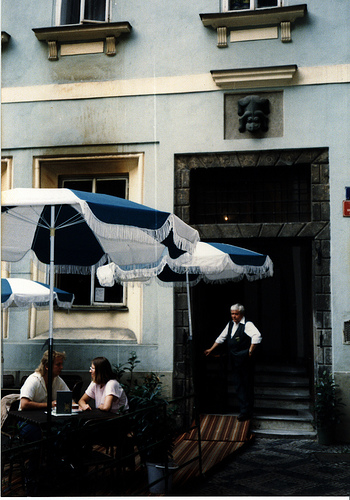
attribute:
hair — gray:
[233, 305, 247, 310]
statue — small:
[237, 92, 276, 138]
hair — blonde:
[41, 356, 47, 374]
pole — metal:
[50, 241, 56, 407]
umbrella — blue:
[6, 196, 195, 271]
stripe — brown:
[227, 418, 233, 441]